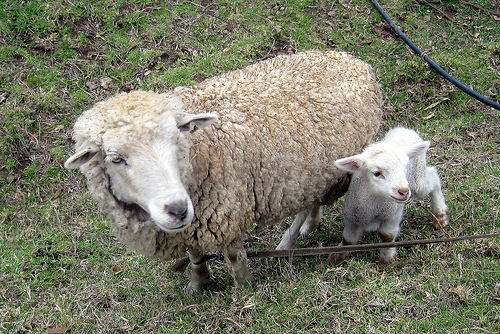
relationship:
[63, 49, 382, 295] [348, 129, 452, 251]
bearded man beside lamb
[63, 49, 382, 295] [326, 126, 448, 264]
bearded man standing next to baby lamb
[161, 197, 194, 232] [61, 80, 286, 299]
nose of sheep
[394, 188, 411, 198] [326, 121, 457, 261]
nose of lamb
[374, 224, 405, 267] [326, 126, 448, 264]
leg of baby lamb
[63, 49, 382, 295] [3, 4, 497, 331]
bearded man on field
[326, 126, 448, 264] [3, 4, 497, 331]
baby lamb on field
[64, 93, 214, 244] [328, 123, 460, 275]
head of sheep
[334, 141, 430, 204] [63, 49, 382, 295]
head of bearded man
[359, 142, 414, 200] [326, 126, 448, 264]
head of baby lamb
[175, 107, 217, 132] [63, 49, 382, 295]
ear of bearded man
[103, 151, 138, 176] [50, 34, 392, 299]
eye of sheep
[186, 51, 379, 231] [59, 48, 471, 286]
body of sheep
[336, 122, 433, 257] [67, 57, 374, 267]
body of sheep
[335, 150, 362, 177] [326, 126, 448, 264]
ear of baby lamb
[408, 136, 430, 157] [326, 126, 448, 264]
ear of baby lamb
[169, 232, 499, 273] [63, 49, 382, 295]
rope tied to bearded man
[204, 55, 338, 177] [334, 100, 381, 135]
coat of wool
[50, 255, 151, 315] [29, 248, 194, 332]
patch of grass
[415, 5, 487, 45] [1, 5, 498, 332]
brown leaves on grass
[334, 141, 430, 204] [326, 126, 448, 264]
head of a baby lamb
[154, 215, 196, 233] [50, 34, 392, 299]
mouth on sheep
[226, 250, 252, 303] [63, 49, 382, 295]
leg of bearded man